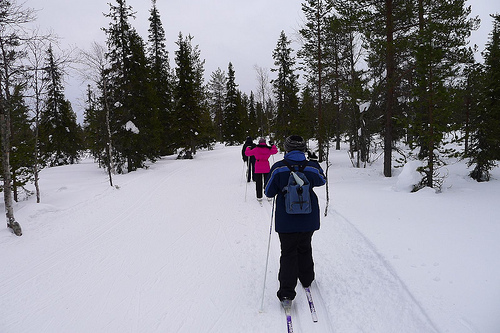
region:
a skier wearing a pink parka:
[197, 102, 284, 205]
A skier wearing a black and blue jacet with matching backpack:
[247, 112, 350, 311]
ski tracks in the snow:
[323, 140, 413, 313]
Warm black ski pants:
[203, 176, 388, 306]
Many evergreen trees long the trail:
[74, 17, 249, 164]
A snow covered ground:
[4, 94, 241, 331]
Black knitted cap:
[279, 111, 313, 171]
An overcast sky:
[32, 0, 284, 104]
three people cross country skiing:
[241, 110, 341, 330]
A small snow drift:
[339, 61, 487, 235]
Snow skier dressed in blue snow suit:
[249, 134, 327, 309]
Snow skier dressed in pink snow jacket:
[236, 136, 280, 201]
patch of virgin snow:
[5, 201, 229, 312]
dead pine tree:
[93, 63, 118, 203]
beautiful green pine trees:
[116, 25, 443, 134]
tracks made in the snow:
[326, 210, 401, 317]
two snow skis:
[263, 285, 333, 329]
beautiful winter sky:
[153, 19, 295, 94]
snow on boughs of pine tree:
[98, 106, 157, 151]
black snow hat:
[273, 138, 315, 160]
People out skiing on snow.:
[231, 126, 338, 329]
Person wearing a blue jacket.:
[259, 134, 335, 306]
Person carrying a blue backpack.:
[281, 162, 316, 220]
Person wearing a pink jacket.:
[245, 136, 280, 177]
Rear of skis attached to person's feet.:
[271, 283, 331, 330]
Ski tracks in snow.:
[338, 215, 443, 332]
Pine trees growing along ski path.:
[86, 47, 216, 190]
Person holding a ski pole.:
[250, 190, 278, 315]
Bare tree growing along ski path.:
[91, 53, 121, 192]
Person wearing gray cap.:
[281, 129, 308, 154]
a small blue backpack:
[278, 157, 323, 219]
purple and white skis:
[271, 278, 331, 324]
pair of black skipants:
[266, 226, 321, 298]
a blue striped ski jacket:
[253, 148, 334, 231]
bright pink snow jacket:
[236, 136, 281, 178]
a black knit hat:
[273, 129, 314, 153]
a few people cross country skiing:
[228, 129, 336, 322]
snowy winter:
[26, 45, 489, 313]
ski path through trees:
[185, 92, 435, 321]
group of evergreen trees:
[112, 47, 219, 162]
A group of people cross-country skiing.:
[66, 75, 432, 317]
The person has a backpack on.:
[285, 166, 315, 221]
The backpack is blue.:
[277, 165, 307, 220]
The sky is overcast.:
[51, 5, 491, 97]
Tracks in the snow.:
[217, 177, 432, 327]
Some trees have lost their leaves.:
[15, 35, 135, 185]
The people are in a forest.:
[6, 5, 481, 286]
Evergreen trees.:
[110, 15, 242, 165]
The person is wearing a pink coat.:
[242, 136, 274, 171]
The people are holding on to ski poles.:
[211, 91, 366, 316]